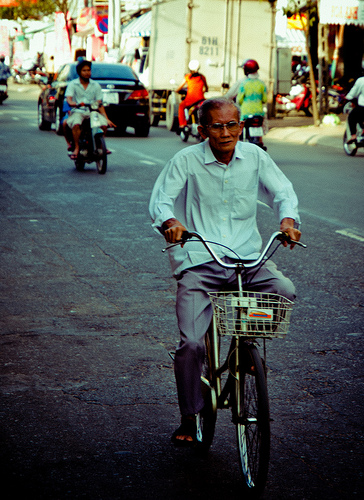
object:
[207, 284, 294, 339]
basket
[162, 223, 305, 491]
bike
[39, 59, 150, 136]
car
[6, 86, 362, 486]
road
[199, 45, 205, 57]
numbers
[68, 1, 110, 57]
building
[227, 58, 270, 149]
person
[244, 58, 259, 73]
helmet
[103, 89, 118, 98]
white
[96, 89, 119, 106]
plate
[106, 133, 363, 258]
line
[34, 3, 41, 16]
leaves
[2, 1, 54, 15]
trees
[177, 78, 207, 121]
orange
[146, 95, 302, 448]
man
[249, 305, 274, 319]
sign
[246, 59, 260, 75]
red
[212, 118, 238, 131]
glasses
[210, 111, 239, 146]
face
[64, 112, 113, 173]
scooter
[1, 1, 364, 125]
distance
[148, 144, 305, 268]
shirt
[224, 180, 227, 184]
buttons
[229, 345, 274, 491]
wheel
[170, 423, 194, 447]
feet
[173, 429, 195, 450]
pedals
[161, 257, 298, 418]
pants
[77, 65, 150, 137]
back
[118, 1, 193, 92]
side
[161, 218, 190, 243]
hands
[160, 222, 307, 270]
bars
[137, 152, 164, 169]
painted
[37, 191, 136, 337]
black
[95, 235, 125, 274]
crack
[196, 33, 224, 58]
writing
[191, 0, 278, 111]
rear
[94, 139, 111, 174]
wheels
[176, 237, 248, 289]
cables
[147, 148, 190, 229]
long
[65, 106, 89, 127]
shorts